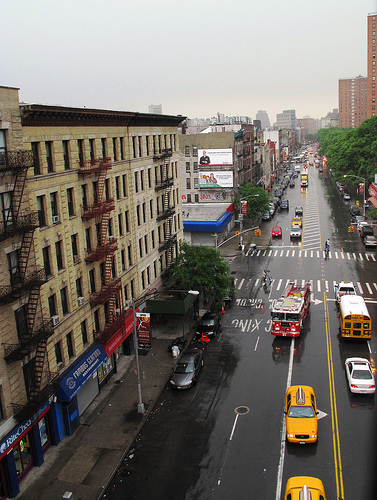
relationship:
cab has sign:
[283, 380, 320, 449] [293, 382, 309, 405]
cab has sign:
[280, 477, 336, 498] [299, 483, 313, 500]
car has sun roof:
[341, 355, 377, 396] [350, 358, 368, 366]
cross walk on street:
[233, 277, 376, 294] [266, 174, 375, 473]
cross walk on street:
[245, 242, 376, 263] [266, 174, 375, 473]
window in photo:
[45, 135, 59, 175] [6, 7, 377, 496]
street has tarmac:
[266, 174, 375, 473] [149, 409, 206, 500]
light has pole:
[122, 288, 206, 431] [127, 303, 148, 418]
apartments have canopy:
[18, 103, 186, 409] [145, 285, 197, 345]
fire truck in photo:
[270, 281, 311, 338] [6, 7, 377, 496]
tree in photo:
[334, 121, 375, 188] [6, 7, 377, 496]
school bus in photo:
[336, 292, 373, 345] [6, 7, 377, 496]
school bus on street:
[336, 292, 373, 345] [266, 174, 375, 473]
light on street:
[122, 288, 206, 431] [266, 174, 375, 473]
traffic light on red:
[251, 226, 264, 244] [255, 226, 263, 238]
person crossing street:
[321, 238, 332, 259] [266, 174, 375, 473]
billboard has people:
[198, 148, 238, 172] [198, 150, 212, 170]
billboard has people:
[193, 167, 236, 191] [198, 172, 219, 191]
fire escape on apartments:
[2, 145, 54, 421] [18, 103, 186, 409]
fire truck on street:
[270, 281, 311, 338] [266, 174, 375, 473]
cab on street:
[283, 380, 320, 449] [266, 174, 375, 473]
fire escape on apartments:
[77, 162, 129, 339] [18, 103, 186, 409]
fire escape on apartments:
[148, 141, 185, 280] [18, 103, 186, 409]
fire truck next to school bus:
[270, 281, 311, 338] [336, 292, 373, 345]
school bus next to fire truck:
[336, 292, 373, 345] [270, 281, 311, 338]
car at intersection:
[270, 223, 284, 242] [247, 235, 376, 293]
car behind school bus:
[341, 355, 377, 396] [336, 292, 373, 345]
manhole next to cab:
[233, 401, 252, 415] [283, 380, 320, 449]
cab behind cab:
[283, 380, 320, 449] [283, 470, 326, 498]